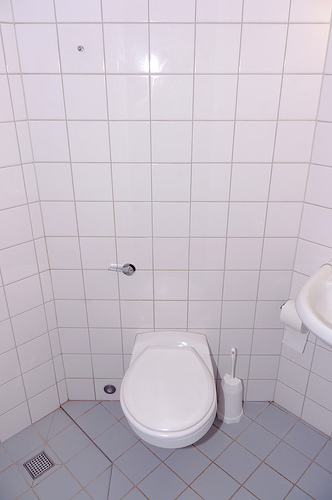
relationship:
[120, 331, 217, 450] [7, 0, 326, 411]
toilet on wall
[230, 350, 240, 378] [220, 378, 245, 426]
brush in holder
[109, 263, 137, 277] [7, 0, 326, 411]
handle on wall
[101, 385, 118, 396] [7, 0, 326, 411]
pipe on wall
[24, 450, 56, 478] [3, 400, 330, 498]
drain on floor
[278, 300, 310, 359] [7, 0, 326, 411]
tp on wall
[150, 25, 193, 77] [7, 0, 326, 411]
tile on wall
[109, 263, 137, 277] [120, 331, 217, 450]
handle for toilet